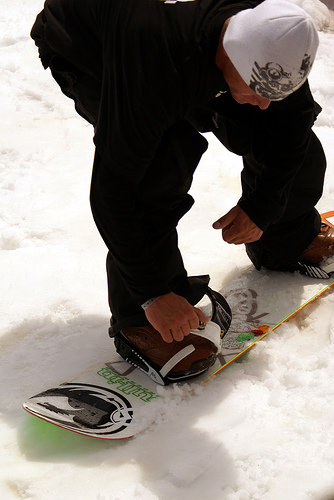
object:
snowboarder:
[29, 0, 328, 391]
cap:
[221, 0, 319, 104]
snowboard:
[21, 214, 334, 442]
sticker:
[21, 396, 127, 446]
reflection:
[131, 433, 258, 500]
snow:
[0, 93, 59, 376]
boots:
[108, 311, 217, 388]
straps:
[159, 343, 196, 377]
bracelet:
[141, 291, 164, 310]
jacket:
[25, 1, 319, 313]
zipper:
[215, 86, 228, 100]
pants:
[40, 20, 207, 321]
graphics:
[248, 51, 315, 102]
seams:
[275, 19, 306, 47]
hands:
[211, 203, 264, 246]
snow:
[223, 370, 333, 500]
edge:
[214, 280, 334, 376]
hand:
[144, 290, 209, 344]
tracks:
[0, 58, 54, 257]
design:
[95, 360, 165, 408]